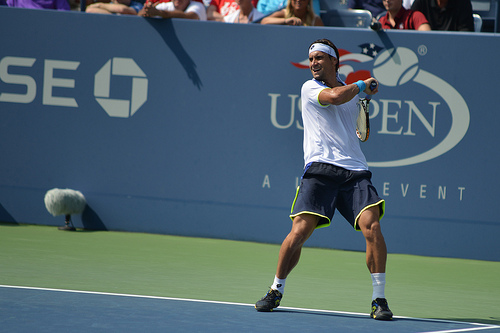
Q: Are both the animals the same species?
A: Yes, all the animals are cows.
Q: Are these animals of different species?
A: No, all the animals are cows.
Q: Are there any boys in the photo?
A: No, there are no boys.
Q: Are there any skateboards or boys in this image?
A: No, there are no boys or skateboards.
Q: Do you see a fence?
A: No, there are no fences.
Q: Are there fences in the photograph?
A: No, there are no fences.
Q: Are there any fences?
A: No, there are no fences.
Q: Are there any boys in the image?
A: No, there are no boys.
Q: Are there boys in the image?
A: No, there are no boys.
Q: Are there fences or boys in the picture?
A: No, there are no boys or fences.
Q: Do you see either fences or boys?
A: No, there are no boys or fences.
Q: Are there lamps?
A: No, there are no lamps.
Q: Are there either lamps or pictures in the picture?
A: No, there are no lamps or pictures.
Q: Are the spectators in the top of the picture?
A: Yes, the spectators are in the top of the image.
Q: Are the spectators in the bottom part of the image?
A: No, the spectators are in the top of the image.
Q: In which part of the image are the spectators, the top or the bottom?
A: The spectators are in the top of the image.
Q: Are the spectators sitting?
A: Yes, the spectators are sitting.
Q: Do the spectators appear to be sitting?
A: Yes, the spectators are sitting.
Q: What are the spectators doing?
A: The spectators are sitting.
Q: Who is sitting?
A: The spectators are sitting.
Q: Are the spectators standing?
A: No, the spectators are sitting.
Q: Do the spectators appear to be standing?
A: No, the spectators are sitting.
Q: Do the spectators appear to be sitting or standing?
A: The spectators are sitting.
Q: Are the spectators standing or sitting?
A: The spectators are sitting.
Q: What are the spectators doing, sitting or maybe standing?
A: The spectators are sitting.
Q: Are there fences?
A: No, there are no fences.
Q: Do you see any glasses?
A: No, there are no glasses.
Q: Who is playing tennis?
A: The man is playing tennis.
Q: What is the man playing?
A: The man is playing tennis.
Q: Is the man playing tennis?
A: Yes, the man is playing tennis.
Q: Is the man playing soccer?
A: No, the man is playing tennis.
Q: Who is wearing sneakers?
A: The man is wearing sneakers.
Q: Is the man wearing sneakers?
A: Yes, the man is wearing sneakers.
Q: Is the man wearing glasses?
A: No, the man is wearing sneakers.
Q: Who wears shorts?
A: The man wears shorts.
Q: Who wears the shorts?
A: The man wears shorts.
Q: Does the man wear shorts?
A: Yes, the man wears shorts.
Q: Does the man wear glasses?
A: No, the man wears shorts.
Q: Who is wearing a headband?
A: The man is wearing a headband.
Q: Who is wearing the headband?
A: The man is wearing a headband.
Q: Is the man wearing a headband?
A: Yes, the man is wearing a headband.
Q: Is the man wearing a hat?
A: No, the man is wearing a headband.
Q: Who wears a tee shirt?
A: The man wears a tee shirt.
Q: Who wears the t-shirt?
A: The man wears a tee shirt.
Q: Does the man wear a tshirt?
A: Yes, the man wears a tshirt.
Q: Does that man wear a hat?
A: No, the man wears a tshirt.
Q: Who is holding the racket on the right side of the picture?
A: The man is holding the tennis racket.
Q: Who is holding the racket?
A: The man is holding the tennis racket.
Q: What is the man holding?
A: The man is holding the racket.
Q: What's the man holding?
A: The man is holding the racket.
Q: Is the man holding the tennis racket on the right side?
A: Yes, the man is holding the racket.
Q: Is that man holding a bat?
A: No, the man is holding the racket.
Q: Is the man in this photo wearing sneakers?
A: Yes, the man is wearing sneakers.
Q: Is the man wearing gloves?
A: No, the man is wearing sneakers.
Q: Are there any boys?
A: No, there are no boys.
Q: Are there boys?
A: No, there are no boys.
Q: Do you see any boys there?
A: No, there are no boys.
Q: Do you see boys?
A: No, there are no boys.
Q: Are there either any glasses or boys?
A: No, there are no boys or glasses.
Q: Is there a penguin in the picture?
A: No, there are no penguins.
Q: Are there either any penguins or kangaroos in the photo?
A: No, there are no penguins or kangaroos.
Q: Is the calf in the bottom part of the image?
A: Yes, the calf is in the bottom of the image.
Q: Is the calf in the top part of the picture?
A: No, the calf is in the bottom of the image.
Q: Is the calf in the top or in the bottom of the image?
A: The calf is in the bottom of the image.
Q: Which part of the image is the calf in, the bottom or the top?
A: The calf is in the bottom of the image.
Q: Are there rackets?
A: Yes, there is a racket.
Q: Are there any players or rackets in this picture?
A: Yes, there is a racket.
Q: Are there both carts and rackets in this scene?
A: No, there is a racket but no carts.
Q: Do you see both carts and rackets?
A: No, there is a racket but no carts.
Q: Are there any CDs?
A: No, there are no cds.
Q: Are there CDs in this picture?
A: No, there are no cds.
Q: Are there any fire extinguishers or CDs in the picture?
A: No, there are no CDs or fire extinguishers.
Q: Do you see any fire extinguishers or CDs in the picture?
A: No, there are no CDs or fire extinguishers.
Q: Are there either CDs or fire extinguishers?
A: No, there are no CDs or fire extinguishers.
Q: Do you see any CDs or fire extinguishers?
A: No, there are no CDs or fire extinguishers.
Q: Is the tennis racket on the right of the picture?
A: Yes, the tennis racket is on the right of the image.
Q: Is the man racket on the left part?
A: No, the tennis racket is on the right of the image.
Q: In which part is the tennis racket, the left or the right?
A: The tennis racket is on the right of the image.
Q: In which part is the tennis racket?
A: The tennis racket is on the right of the image.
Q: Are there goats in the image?
A: No, there are no goats.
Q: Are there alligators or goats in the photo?
A: No, there are no goats or alligators.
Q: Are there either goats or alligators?
A: No, there are no goats or alligators.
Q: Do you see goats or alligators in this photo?
A: No, there are no goats or alligators.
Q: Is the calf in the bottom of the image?
A: Yes, the calf is in the bottom of the image.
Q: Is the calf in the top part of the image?
A: No, the calf is in the bottom of the image.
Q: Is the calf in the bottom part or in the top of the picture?
A: The calf is in the bottom of the image.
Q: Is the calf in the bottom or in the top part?
A: The calf is in the bottom of the image.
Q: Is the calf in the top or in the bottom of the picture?
A: The calf is in the bottom of the image.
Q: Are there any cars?
A: No, there are no cars.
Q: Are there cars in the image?
A: No, there are no cars.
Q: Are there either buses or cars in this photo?
A: No, there are no cars or buses.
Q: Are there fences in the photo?
A: No, there are no fences.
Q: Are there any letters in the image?
A: Yes, there are letters.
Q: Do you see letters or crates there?
A: Yes, there are letters.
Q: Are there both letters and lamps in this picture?
A: No, there are letters but no lamps.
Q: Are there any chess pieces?
A: No, there are no chess pieces.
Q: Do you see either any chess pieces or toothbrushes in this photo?
A: No, there are no chess pieces or toothbrushes.